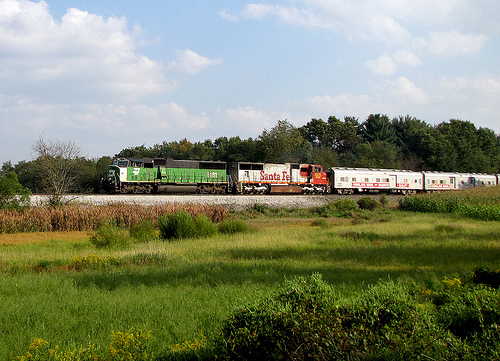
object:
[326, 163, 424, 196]
train cars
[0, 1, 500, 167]
sky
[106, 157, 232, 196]
truck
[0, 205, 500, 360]
ground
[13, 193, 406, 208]
gravel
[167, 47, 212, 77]
cloud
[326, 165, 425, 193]
cars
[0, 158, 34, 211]
green trees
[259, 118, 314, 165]
trees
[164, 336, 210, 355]
yellow flowers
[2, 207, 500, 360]
grass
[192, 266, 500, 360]
bush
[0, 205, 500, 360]
field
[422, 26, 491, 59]
white clouds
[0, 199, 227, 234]
big bushes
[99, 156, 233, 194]
engine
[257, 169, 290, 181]
santa fe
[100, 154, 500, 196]
train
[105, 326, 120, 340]
flower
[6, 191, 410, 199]
track